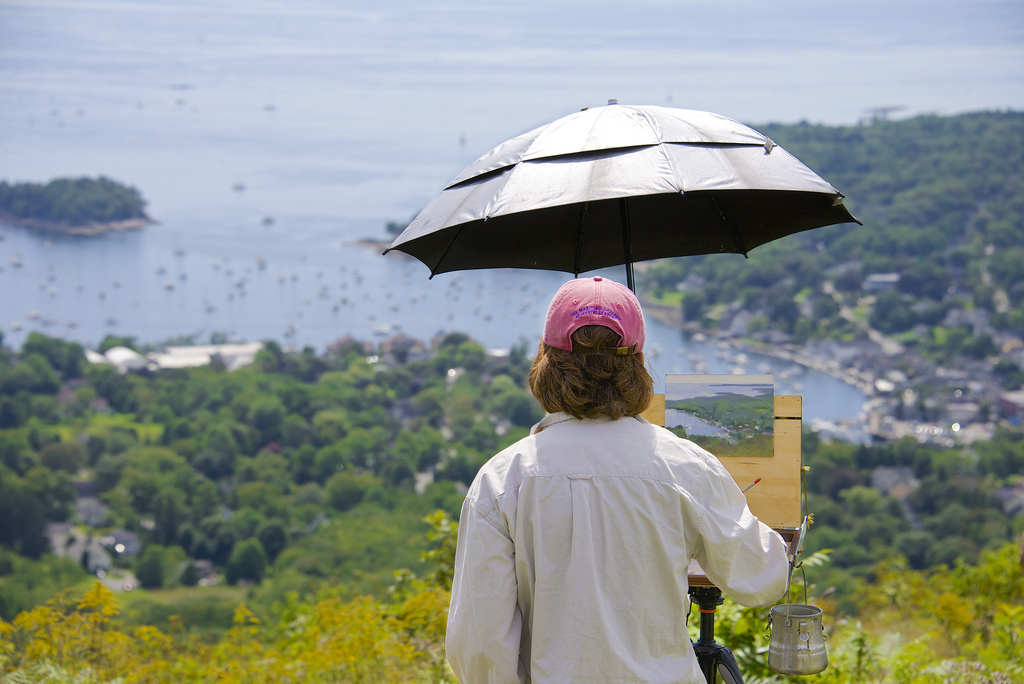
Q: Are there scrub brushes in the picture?
A: No, there are no scrub brushes.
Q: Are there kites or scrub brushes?
A: No, there are no scrub brushes or kites.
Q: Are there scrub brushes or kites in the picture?
A: No, there are no scrub brushes or kites.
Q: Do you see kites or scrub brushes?
A: No, there are no scrub brushes or kites.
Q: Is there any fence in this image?
A: No, there are no fences.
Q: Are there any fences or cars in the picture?
A: No, there are no fences or cars.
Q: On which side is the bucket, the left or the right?
A: The bucket is on the right of the image.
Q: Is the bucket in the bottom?
A: Yes, the bucket is in the bottom of the image.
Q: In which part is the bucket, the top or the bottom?
A: The bucket is in the bottom of the image.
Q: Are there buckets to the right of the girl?
A: Yes, there is a bucket to the right of the girl.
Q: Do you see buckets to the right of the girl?
A: Yes, there is a bucket to the right of the girl.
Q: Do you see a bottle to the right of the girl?
A: No, there is a bucket to the right of the girl.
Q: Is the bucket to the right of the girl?
A: Yes, the bucket is to the right of the girl.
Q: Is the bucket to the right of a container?
A: No, the bucket is to the right of the girl.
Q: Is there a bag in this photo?
A: No, there are no bags.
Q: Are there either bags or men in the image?
A: No, there are no bags or men.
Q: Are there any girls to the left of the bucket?
A: Yes, there is a girl to the left of the bucket.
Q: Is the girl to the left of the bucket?
A: Yes, the girl is to the left of the bucket.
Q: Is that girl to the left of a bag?
A: No, the girl is to the left of the bucket.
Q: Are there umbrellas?
A: Yes, there is an umbrella.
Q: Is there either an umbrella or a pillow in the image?
A: Yes, there is an umbrella.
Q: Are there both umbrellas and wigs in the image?
A: No, there is an umbrella but no wigs.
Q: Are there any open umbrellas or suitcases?
A: Yes, there is an open umbrella.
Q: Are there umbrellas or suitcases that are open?
A: Yes, the umbrella is open.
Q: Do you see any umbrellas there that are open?
A: Yes, there is an open umbrella.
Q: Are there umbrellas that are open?
A: Yes, there is an umbrella that is open.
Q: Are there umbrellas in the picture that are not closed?
A: Yes, there is a open umbrella.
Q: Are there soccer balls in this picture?
A: No, there are no soccer balls.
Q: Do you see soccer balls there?
A: No, there are no soccer balls.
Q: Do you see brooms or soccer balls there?
A: No, there are no soccer balls or brooms.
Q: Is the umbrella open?
A: Yes, the umbrella is open.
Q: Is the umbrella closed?
A: No, the umbrella is open.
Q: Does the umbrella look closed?
A: No, the umbrella is open.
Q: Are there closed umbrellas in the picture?
A: No, there is an umbrella but it is open.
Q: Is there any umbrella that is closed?
A: No, there is an umbrella but it is open.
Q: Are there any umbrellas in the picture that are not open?
A: No, there is an umbrella but it is open.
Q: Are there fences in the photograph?
A: No, there are no fences.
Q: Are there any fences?
A: No, there are no fences.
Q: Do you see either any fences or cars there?
A: No, there are no fences or cars.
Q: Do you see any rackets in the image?
A: No, there are no rackets.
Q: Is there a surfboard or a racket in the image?
A: No, there are no rackets or surfboards.